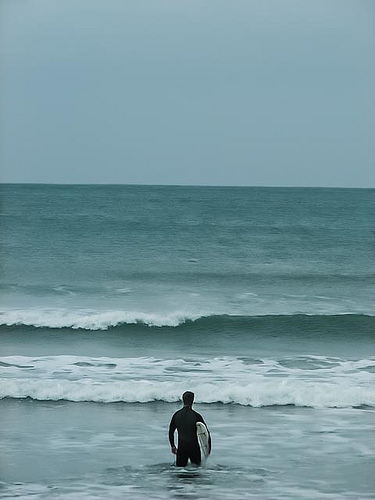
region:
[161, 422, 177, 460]
left arm on man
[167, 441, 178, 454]
left hand on man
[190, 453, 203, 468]
right leg on man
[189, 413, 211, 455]
man with white board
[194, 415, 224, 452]
man holding white board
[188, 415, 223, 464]
white board in arm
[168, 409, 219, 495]
man in black suit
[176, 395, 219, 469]
man walking in water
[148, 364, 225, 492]
the man is holding a surfboard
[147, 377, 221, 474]
the man is holding a surfboard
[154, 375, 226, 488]
the man is holding a surfboard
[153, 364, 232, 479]
the man is holding a surfboard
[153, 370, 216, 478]
the man is holding a surfboard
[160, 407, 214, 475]
the wet suit is black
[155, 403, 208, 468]
the wet suit is black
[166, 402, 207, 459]
the wet suit is black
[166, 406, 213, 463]
the wet suit is black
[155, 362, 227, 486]
surfer facing the waves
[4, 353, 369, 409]
ocean wave coming to shore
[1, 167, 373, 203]
water and sky horizen line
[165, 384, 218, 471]
man carrying a surfboard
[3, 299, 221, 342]
white froth on top of wave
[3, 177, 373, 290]
ocean with no whitecaps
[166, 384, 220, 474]
dark clothing on a surfer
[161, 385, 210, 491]
person standing thigh high in water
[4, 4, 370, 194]
hazy blue sky without clouds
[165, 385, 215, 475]
man with dark hair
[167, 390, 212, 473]
a surfer in the ocean getting ready to surf.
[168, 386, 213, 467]
surfer in the ocean getting ready to surf.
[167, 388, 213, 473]
surfer in the ocean getting ready to surf.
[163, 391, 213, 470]
surfer in the ocean getting ready to surf.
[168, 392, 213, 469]
surfer in the ocean getting ready to surf.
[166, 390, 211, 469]
A lone surfer walks his board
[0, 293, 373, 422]
Surf arises from the tide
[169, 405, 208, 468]
Surfer wears black wetsuit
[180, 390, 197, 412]
Surfer haircut is short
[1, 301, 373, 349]
A wave breaks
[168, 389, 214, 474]
A young man's hobby is surfing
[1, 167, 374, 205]
Ocean makes the horizon watery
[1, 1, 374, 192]
Oceanside sky is birdless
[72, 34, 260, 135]
sky above the water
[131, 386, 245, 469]
person in the water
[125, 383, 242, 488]
person with a surfboard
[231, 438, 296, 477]
water next to man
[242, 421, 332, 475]
suds in the water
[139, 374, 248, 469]
man in a wetsuit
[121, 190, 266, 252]
water in the distance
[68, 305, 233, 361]
wave forming in the water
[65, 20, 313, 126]
clear and blue sky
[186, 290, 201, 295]
A ripple in the water.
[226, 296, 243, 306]
A ripple in the water.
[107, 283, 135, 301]
A ripple in the water.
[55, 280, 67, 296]
A ripple in the water.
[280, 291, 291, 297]
A ripple in the water.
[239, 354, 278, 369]
A ripple in the water.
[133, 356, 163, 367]
A ripple in the water.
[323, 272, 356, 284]
A ripple in the water.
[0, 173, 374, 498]
water is mostly calm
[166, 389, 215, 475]
man standing in water